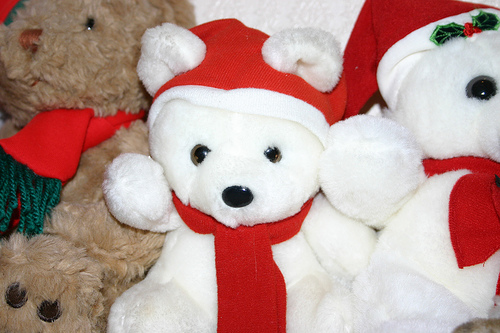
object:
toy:
[318, 0, 499, 333]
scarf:
[0, 106, 148, 232]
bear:
[0, 0, 198, 332]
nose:
[16, 28, 42, 56]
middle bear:
[102, 18, 378, 332]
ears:
[260, 28, 345, 93]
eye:
[463, 75, 498, 101]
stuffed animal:
[340, 49, 500, 319]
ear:
[137, 21, 208, 97]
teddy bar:
[0, 0, 499, 331]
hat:
[147, 18, 346, 152]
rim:
[156, 94, 315, 121]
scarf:
[172, 188, 313, 332]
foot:
[0, 230, 106, 332]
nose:
[221, 185, 254, 208]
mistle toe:
[425, 10, 500, 48]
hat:
[342, 0, 499, 119]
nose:
[481, 118, 500, 146]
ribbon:
[460, 22, 483, 38]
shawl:
[422, 155, 499, 295]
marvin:
[16, 181, 50, 237]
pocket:
[293, 7, 367, 41]